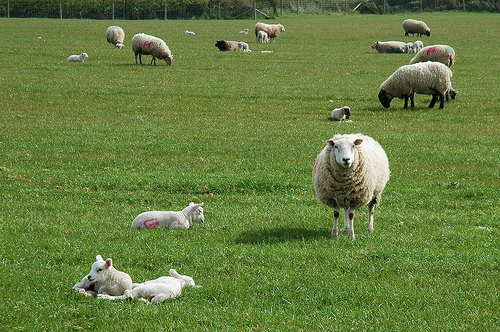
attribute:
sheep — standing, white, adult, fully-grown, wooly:
[312, 130, 392, 245]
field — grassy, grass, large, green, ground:
[2, 15, 499, 330]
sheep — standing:
[407, 45, 456, 66]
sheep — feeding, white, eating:
[131, 32, 173, 66]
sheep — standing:
[256, 21, 287, 43]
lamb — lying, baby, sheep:
[131, 268, 198, 308]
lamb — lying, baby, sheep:
[69, 255, 132, 301]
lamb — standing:
[256, 29, 271, 45]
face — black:
[378, 89, 393, 109]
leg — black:
[403, 96, 410, 110]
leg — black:
[409, 92, 415, 108]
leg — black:
[427, 92, 437, 109]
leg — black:
[437, 92, 447, 110]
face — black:
[342, 107, 351, 119]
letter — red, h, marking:
[425, 45, 436, 56]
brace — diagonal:
[256, 6, 269, 19]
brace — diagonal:
[236, 8, 253, 20]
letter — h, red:
[142, 39, 153, 49]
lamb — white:
[130, 201, 209, 233]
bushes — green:
[1, 0, 499, 20]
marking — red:
[144, 217, 160, 229]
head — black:
[375, 86, 391, 109]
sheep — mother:
[370, 38, 405, 54]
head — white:
[114, 43, 126, 50]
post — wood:
[57, 2, 65, 21]